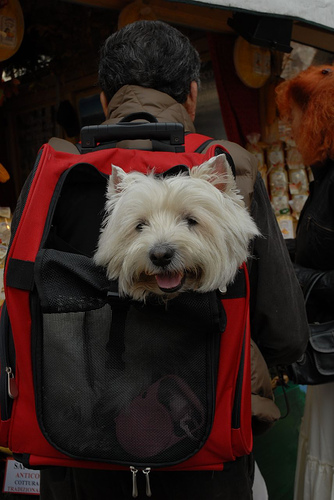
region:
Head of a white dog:
[98, 154, 259, 297]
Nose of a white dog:
[148, 242, 176, 267]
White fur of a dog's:
[152, 181, 183, 222]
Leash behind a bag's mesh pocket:
[112, 370, 206, 458]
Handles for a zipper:
[128, 464, 153, 497]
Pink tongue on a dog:
[153, 268, 183, 292]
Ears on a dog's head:
[108, 151, 235, 208]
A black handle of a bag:
[79, 118, 187, 151]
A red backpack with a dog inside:
[5, 124, 251, 470]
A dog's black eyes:
[134, 214, 198, 233]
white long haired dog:
[103, 151, 257, 297]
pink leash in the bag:
[110, 373, 203, 457]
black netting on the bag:
[36, 279, 213, 451]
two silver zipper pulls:
[127, 464, 151, 499]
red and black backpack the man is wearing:
[6, 126, 261, 471]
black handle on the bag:
[82, 121, 182, 150]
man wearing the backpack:
[19, 22, 303, 491]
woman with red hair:
[267, 61, 333, 498]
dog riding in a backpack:
[50, 159, 261, 357]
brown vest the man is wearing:
[44, 91, 282, 422]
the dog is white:
[108, 160, 255, 282]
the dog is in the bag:
[30, 165, 253, 450]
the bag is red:
[31, 150, 255, 473]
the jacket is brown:
[117, 86, 168, 111]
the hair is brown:
[289, 73, 327, 142]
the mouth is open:
[129, 247, 187, 296]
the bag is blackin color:
[307, 320, 331, 377]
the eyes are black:
[185, 217, 195, 223]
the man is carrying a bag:
[7, 16, 305, 498]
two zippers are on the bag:
[126, 459, 157, 490]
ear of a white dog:
[191, 150, 238, 189]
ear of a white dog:
[103, 161, 132, 199]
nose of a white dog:
[145, 239, 177, 270]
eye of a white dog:
[182, 211, 201, 233]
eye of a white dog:
[135, 219, 150, 236]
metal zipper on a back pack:
[141, 465, 151, 497]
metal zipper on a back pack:
[127, 461, 139, 498]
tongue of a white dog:
[150, 267, 184, 291]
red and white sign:
[1, 452, 41, 499]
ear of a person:
[185, 79, 199, 120]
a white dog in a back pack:
[60, 147, 258, 402]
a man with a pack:
[0, 14, 317, 493]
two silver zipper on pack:
[116, 463, 156, 498]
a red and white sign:
[1, 457, 47, 498]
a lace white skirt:
[282, 382, 331, 497]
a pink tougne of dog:
[149, 264, 189, 295]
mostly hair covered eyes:
[119, 208, 212, 235]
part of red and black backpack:
[0, 318, 245, 425]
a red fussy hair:
[271, 61, 333, 185]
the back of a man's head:
[87, 18, 205, 128]